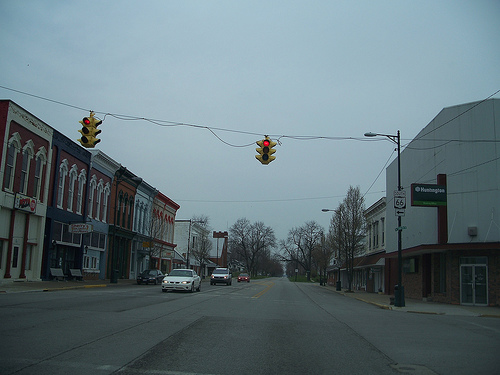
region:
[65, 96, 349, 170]
two stop lights hanging froma wire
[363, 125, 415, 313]
black metal street lamp on the sidewalk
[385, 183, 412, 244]
white signs on a post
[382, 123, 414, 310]
black metal post of a street lamp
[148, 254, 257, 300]
three cars driving down the road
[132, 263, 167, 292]
a car parked on the side of the road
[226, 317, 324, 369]
black asphalt surface of the road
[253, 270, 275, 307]
yellow lines painted on the road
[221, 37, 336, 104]
cloudy blue skies over the street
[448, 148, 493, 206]
white concrete wall of a building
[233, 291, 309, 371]
this is a road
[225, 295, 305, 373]
the road is tarmacked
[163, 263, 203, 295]
this is a car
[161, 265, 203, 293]
the car is moving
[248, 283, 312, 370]
the road is clean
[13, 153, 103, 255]
this is the building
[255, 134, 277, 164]
this is a traffic light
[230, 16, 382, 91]
this is the sky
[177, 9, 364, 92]
the sky is grey in color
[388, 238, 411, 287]
this is a pole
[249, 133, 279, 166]
traffic light hanging above road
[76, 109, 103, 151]
traffic light hanging above road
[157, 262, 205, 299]
car on the road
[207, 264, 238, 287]
car on the road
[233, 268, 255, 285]
car on the road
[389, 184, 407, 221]
white and black sign on pole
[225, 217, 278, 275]
tree behind a road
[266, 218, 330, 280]
tree behind a road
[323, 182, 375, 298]
tree behind a road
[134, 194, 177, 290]
tree behind a road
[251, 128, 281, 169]
The streetlight is red.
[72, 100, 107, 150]
The streetlight is red.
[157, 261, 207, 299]
The car is white.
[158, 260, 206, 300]
The car's headlight are on.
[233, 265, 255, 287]
The car is red.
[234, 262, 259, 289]
The car's headlights are on.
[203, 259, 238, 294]
The car's headlights are on.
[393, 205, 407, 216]
The sign is black and white.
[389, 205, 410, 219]
An arrow is on the sign.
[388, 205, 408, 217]
The arrow is black.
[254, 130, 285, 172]
a traffic signal light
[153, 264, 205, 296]
a white sedan car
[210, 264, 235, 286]
a white suv car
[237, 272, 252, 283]
a red sedan car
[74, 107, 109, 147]
a traffic signal light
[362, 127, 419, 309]
a street lamp post on street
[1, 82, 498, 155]
power lines connecting traffic light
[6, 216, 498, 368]
a street with couple cars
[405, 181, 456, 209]
a company logo for building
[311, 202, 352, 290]
a street lamp post on sidewalk